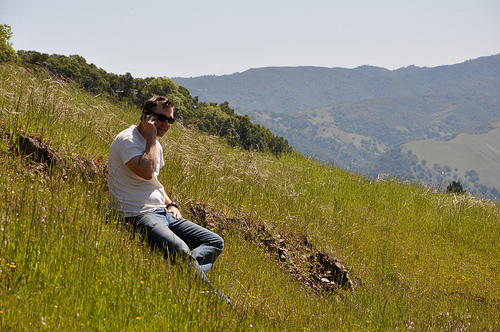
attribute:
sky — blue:
[234, 5, 355, 53]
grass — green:
[28, 233, 124, 305]